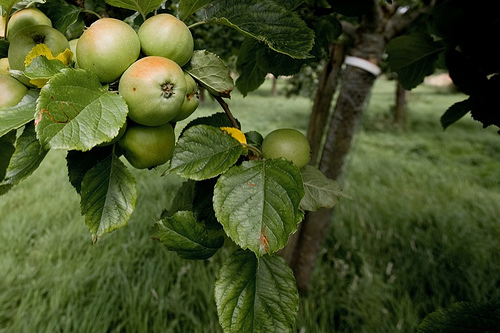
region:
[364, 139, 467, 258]
this is the grass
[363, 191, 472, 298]
the grass is green in color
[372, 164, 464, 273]
the grass is short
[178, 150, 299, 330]
these are some leaves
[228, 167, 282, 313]
the leaves are green in color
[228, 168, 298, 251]
the leaf is small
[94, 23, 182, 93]
these are some fruits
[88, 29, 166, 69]
the fruits are green in color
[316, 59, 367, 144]
this is a branch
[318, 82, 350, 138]
the branch is brown in color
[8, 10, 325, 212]
a bunch of apples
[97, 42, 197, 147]
a ripe green apple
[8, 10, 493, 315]
apples on a tree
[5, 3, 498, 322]
a young apple tree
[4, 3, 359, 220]
apples on a branch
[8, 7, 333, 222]
apples waiting to be picked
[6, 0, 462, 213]
fresh green apples for picking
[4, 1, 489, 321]
apples on a young tree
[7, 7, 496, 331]
apples in an orchard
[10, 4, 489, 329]
apples in a grove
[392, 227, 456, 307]
part of a green grass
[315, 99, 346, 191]
part of a stem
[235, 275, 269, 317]
part of a leave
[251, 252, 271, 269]
tip of a leaf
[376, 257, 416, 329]
part of some grass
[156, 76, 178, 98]
part of a fruit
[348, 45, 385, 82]
part of a rope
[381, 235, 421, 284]
part of some grass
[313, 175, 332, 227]
part of a leaf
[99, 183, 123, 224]
part of a leaf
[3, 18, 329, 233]
There are apples on the Branch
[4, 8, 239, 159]
the apples are green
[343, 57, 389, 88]
There is a white band on the tree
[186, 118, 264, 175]
There is some yellow on the leaf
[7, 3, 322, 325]
The leaves are green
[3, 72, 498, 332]
There is grass on the ground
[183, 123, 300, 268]
The leaves have veins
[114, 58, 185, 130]
The apple has a spot on it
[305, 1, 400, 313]
The tree trunk is brown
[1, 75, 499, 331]
The grass is green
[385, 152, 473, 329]
this is the grass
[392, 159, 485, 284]
the grass is green in color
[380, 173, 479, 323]
the grass is long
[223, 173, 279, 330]
these are some leaves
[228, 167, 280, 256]
the leaf is medium in size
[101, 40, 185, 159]
these are some fruits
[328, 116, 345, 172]
it is brown in color